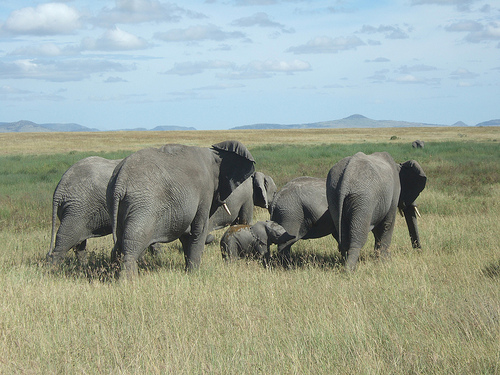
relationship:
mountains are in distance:
[0, 113, 500, 133] [0, 0, 500, 134]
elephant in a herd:
[221, 221, 297, 270] [49, 139, 428, 285]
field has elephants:
[0, 126, 499, 374] [49, 139, 428, 285]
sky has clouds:
[0, 0, 499, 132] [0, 0, 499, 104]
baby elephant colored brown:
[221, 221, 297, 270] [223, 222, 254, 235]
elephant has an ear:
[221, 221, 297, 270] [209, 138, 255, 220]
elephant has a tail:
[107, 140, 258, 279] [110, 175, 128, 243]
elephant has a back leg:
[107, 140, 258, 279] [111, 200, 153, 282]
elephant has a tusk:
[107, 140, 258, 279] [224, 201, 232, 216]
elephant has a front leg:
[107, 140, 258, 279] [183, 208, 210, 274]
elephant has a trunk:
[328, 151, 427, 274] [403, 201, 423, 250]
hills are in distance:
[0, 113, 500, 133] [0, 0, 500, 134]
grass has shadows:
[0, 126, 499, 374] [56, 248, 499, 282]